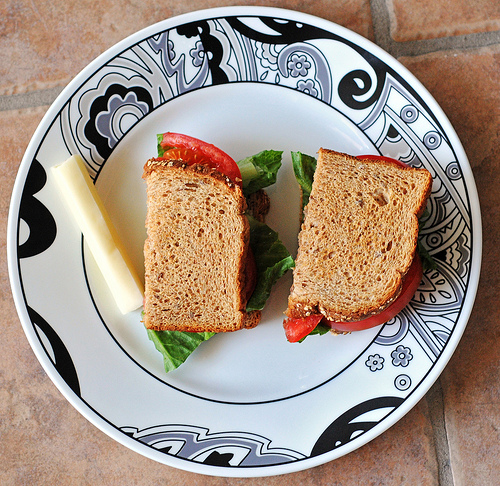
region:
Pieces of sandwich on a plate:
[132, 128, 430, 370]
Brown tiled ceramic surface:
[420, 375, 495, 480]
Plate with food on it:
[2, 0, 487, 480]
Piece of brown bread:
[145, 161, 242, 331]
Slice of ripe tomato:
[157, 127, 238, 182]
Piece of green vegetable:
[148, 327, 211, 374]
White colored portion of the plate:
[222, 345, 303, 385]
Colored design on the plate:
[120, 17, 350, 103]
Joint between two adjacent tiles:
[420, 406, 460, 481]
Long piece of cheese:
[52, 155, 144, 315]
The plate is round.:
[0, 4, 495, 484]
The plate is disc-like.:
[6, 4, 488, 484]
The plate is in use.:
[5, 4, 488, 482]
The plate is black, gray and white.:
[3, 3, 490, 483]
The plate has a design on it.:
[6, 0, 484, 481]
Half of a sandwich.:
[128, 120, 293, 378]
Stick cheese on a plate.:
[3, 8, 145, 458]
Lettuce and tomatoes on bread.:
[138, 120, 295, 387]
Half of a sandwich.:
[279, 130, 438, 357]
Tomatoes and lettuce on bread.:
[281, 125, 442, 358]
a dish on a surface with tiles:
[0, 0, 494, 478]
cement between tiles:
[394, 392, 498, 482]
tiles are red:
[2, 2, 498, 482]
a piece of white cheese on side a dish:
[36, 141, 146, 329]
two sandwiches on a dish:
[135, 125, 435, 350]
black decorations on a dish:
[306, 386, 401, 457]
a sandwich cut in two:
[135, 120, 432, 355]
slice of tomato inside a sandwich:
[125, 125, 265, 220]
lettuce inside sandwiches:
[134, 117, 436, 399]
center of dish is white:
[80, 76, 405, 404]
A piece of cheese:
[49, 162, 144, 316]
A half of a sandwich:
[136, 133, 261, 341]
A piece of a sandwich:
[287, 134, 433, 346]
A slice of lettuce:
[150, 333, 212, 370]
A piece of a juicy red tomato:
[159, 128, 241, 175]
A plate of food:
[1, 6, 498, 477]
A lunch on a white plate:
[6, 6, 486, 478]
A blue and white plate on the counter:
[3, 1, 498, 483]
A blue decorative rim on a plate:
[211, 16, 329, 85]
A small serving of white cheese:
[46, 144, 148, 319]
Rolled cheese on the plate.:
[50, 145, 140, 325]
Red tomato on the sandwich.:
[161, 130, 238, 190]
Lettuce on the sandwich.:
[147, 315, 230, 373]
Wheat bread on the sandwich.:
[139, 153, 246, 340]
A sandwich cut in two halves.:
[133, 118, 435, 368]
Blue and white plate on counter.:
[9, 9, 489, 481]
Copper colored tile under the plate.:
[9, 0, 494, 480]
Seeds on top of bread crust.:
[292, 300, 375, 323]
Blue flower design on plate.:
[280, 47, 311, 78]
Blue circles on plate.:
[392, 369, 416, 393]